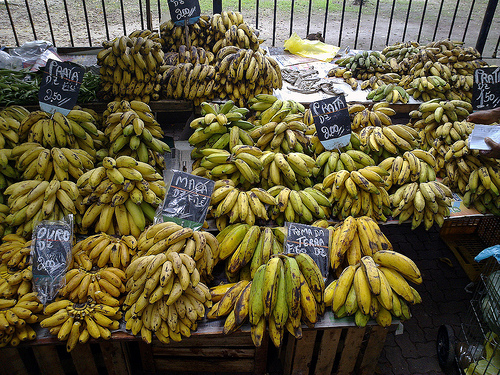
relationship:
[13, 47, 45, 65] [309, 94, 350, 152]
bag over sign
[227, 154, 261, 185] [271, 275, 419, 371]
banana on crates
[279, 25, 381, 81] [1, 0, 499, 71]
bag next to gate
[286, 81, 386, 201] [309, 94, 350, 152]
numbers on sign